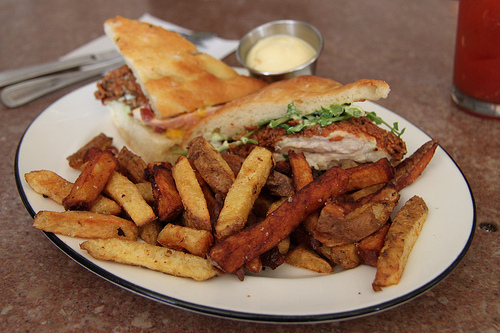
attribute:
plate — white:
[16, 57, 477, 323]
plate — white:
[429, 186, 464, 223]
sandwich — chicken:
[78, 9, 411, 170]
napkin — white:
[62, 2, 247, 83]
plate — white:
[7, 92, 94, 168]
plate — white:
[42, 24, 482, 331]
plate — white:
[411, 230, 463, 264]